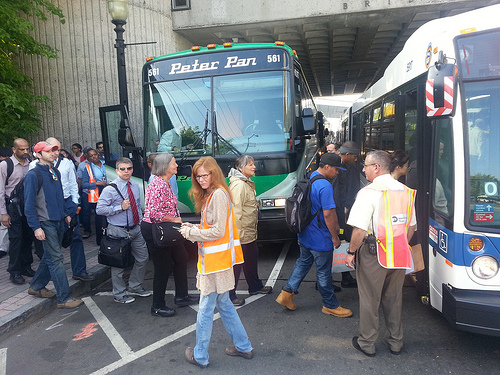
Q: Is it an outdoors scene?
A: Yes, it is outdoors.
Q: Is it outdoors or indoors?
A: It is outdoors.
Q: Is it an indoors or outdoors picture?
A: It is outdoors.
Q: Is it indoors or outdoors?
A: It is outdoors.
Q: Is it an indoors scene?
A: No, it is outdoors.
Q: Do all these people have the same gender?
A: No, they are both male and female.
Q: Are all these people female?
A: No, they are both male and female.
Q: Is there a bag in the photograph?
A: Yes, there is a bag.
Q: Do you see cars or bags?
A: Yes, there is a bag.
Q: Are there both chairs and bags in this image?
A: No, there is a bag but no chairs.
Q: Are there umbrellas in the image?
A: No, there are no umbrellas.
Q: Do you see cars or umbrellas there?
A: No, there are no umbrellas or cars.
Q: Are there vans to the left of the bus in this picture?
A: No, there is a bag to the left of the bus.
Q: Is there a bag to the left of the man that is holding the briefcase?
A: Yes, there is a bag to the left of the man.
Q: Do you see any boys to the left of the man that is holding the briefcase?
A: No, there is a bag to the left of the man.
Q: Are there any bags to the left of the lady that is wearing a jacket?
A: Yes, there is a bag to the left of the lady.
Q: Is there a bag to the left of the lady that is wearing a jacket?
A: Yes, there is a bag to the left of the lady.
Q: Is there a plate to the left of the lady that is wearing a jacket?
A: No, there is a bag to the left of the lady.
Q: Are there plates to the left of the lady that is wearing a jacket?
A: No, there is a bag to the left of the lady.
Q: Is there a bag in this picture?
A: Yes, there is a bag.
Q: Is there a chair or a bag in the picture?
A: Yes, there is a bag.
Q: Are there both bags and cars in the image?
A: No, there is a bag but no cars.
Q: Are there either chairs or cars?
A: No, there are no cars or chairs.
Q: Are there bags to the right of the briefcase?
A: Yes, there is a bag to the right of the briefcase.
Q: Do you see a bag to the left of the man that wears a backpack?
A: Yes, there is a bag to the left of the man.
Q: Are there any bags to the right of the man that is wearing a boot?
A: No, the bag is to the left of the man.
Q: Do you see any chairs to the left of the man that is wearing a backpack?
A: No, there is a bag to the left of the man.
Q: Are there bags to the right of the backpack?
A: No, the bag is to the left of the backpack.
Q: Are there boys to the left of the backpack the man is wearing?
A: No, there is a bag to the left of the backpack.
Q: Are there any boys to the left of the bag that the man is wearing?
A: No, there is a bag to the left of the backpack.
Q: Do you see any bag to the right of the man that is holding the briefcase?
A: Yes, there is a bag to the right of the man.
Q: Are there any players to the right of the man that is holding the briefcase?
A: No, there is a bag to the right of the man.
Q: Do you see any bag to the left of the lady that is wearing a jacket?
A: Yes, there is a bag to the left of the lady.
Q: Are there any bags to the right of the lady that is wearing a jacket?
A: No, the bag is to the left of the lady.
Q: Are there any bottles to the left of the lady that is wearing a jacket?
A: No, there is a bag to the left of the lady.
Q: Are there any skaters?
A: No, there are no skaters.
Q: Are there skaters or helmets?
A: No, there are no skaters or helmets.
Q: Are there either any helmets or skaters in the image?
A: No, there are no skaters or helmets.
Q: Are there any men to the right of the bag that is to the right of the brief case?
A: Yes, there is a man to the right of the bag.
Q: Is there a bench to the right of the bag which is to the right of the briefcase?
A: No, there is a man to the right of the bag.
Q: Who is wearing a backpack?
A: The man is wearing a backpack.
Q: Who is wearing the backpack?
A: The man is wearing a backpack.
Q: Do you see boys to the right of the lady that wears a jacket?
A: No, there is a man to the right of the lady.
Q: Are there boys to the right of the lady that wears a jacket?
A: No, there is a man to the right of the lady.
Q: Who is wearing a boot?
A: The man is wearing a boot.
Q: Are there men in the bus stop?
A: Yes, there is a man in the bus stop.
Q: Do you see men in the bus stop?
A: Yes, there is a man in the bus stop.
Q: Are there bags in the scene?
A: Yes, there is a bag.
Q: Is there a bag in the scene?
A: Yes, there is a bag.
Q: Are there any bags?
A: Yes, there is a bag.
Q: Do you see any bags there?
A: Yes, there is a bag.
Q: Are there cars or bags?
A: Yes, there is a bag.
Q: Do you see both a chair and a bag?
A: No, there is a bag but no chairs.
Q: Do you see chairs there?
A: No, there are no chairs.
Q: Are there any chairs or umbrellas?
A: No, there are no chairs or umbrellas.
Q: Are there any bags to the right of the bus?
A: No, the bag is to the left of the bus.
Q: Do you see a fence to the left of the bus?
A: No, there is a bag to the left of the bus.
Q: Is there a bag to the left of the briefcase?
A: Yes, there is a bag to the left of the briefcase.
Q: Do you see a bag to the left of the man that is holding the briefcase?
A: Yes, there is a bag to the left of the man.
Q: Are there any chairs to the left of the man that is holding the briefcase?
A: No, there is a bag to the left of the man.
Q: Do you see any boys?
A: No, there are no boys.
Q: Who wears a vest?
A: The man wears a vest.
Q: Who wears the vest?
A: The man wears a vest.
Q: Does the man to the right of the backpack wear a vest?
A: Yes, the man wears a vest.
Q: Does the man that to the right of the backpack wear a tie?
A: No, the man wears a vest.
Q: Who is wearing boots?
A: The man is wearing boots.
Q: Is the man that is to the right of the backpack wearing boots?
A: Yes, the man is wearing boots.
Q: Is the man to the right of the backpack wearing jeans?
A: No, the man is wearing boots.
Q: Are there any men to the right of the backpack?
A: Yes, there is a man to the right of the backpack.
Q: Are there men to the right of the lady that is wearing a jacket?
A: Yes, there is a man to the right of the lady.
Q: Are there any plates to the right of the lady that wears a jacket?
A: No, there is a man to the right of the lady.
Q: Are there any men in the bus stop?
A: Yes, there is a man in the bus stop.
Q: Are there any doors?
A: Yes, there is a door.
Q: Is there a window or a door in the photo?
A: Yes, there is a door.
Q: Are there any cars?
A: No, there are no cars.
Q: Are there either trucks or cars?
A: No, there are no cars or trucks.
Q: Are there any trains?
A: No, there are no trains.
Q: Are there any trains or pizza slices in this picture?
A: No, there are no trains or pizza slices.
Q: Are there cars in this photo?
A: No, there are no cars.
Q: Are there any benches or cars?
A: No, there are no cars or benches.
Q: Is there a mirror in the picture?
A: Yes, there is a mirror.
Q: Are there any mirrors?
A: Yes, there is a mirror.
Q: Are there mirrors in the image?
A: Yes, there is a mirror.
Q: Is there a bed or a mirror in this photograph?
A: Yes, there is a mirror.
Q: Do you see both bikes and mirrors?
A: No, there is a mirror but no bikes.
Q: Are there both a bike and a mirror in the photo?
A: No, there is a mirror but no bikes.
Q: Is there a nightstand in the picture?
A: No, there are no nightstands.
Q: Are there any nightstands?
A: No, there are no nightstands.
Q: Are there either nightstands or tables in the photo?
A: No, there are no nightstands or tables.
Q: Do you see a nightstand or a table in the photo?
A: No, there are no nightstands or tables.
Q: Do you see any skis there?
A: No, there are no skis.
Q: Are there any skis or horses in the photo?
A: No, there are no skis or horses.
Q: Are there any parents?
A: No, there are no parents.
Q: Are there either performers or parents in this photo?
A: No, there are no parents or performers.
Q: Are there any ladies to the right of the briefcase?
A: Yes, there is a lady to the right of the briefcase.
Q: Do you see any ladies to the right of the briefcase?
A: Yes, there is a lady to the right of the briefcase.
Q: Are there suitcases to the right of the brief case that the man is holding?
A: No, there is a lady to the right of the briefcase.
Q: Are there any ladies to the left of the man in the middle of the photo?
A: Yes, there is a lady to the left of the man.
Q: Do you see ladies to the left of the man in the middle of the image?
A: Yes, there is a lady to the left of the man.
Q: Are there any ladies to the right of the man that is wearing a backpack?
A: No, the lady is to the left of the man.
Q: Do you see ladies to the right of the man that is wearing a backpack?
A: No, the lady is to the left of the man.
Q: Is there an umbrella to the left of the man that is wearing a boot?
A: No, there is a lady to the left of the man.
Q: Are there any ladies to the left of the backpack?
A: Yes, there is a lady to the left of the backpack.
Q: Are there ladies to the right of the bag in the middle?
A: No, the lady is to the left of the backpack.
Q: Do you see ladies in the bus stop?
A: Yes, there is a lady in the bus stop.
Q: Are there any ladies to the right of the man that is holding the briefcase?
A: Yes, there is a lady to the right of the man.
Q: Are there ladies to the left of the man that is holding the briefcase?
A: No, the lady is to the right of the man.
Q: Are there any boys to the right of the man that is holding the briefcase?
A: No, there is a lady to the right of the man.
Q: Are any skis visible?
A: No, there are no skis.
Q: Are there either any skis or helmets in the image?
A: No, there are no skis or helmets.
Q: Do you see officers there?
A: No, there are no officers.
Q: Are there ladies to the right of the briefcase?
A: Yes, there is a lady to the right of the briefcase.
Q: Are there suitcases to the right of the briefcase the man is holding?
A: No, there is a lady to the right of the briefcase.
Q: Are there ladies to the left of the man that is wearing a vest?
A: Yes, there is a lady to the left of the man.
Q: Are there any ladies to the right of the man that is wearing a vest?
A: No, the lady is to the left of the man.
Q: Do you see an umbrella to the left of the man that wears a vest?
A: No, there is a lady to the left of the man.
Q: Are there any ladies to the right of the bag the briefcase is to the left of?
A: Yes, there is a lady to the right of the bag.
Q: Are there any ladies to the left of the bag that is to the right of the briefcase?
A: No, the lady is to the right of the bag.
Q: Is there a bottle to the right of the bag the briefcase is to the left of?
A: No, there is a lady to the right of the bag.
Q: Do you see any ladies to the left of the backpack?
A: Yes, there is a lady to the left of the backpack.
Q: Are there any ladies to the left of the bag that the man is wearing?
A: Yes, there is a lady to the left of the backpack.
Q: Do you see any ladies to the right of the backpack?
A: No, the lady is to the left of the backpack.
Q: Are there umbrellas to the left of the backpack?
A: No, there is a lady to the left of the backpack.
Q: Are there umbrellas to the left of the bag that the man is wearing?
A: No, there is a lady to the left of the backpack.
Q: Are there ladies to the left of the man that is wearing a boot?
A: Yes, there is a lady to the left of the man.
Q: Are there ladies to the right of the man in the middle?
A: No, the lady is to the left of the man.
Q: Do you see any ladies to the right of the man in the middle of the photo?
A: No, the lady is to the left of the man.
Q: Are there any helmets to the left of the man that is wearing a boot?
A: No, there is a lady to the left of the man.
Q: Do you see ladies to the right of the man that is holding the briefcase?
A: Yes, there is a lady to the right of the man.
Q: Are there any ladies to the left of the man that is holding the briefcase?
A: No, the lady is to the right of the man.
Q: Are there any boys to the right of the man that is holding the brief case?
A: No, there is a lady to the right of the man.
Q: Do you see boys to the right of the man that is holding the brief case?
A: No, there is a lady to the right of the man.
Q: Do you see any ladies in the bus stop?
A: Yes, there is a lady in the bus stop.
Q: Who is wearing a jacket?
A: The lady is wearing a jacket.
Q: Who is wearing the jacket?
A: The lady is wearing a jacket.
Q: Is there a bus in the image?
A: Yes, there is a bus.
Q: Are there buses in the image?
A: Yes, there is a bus.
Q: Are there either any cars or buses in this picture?
A: Yes, there is a bus.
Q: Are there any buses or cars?
A: Yes, there is a bus.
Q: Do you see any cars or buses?
A: Yes, there is a bus.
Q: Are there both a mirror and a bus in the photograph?
A: Yes, there are both a bus and a mirror.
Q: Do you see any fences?
A: No, there are no fences.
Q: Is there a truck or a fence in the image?
A: No, there are no fences or trucks.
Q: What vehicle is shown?
A: The vehicle is a bus.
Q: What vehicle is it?
A: The vehicle is a bus.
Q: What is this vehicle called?
A: This is a bus.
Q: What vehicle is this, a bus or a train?
A: This is a bus.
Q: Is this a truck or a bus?
A: This is a bus.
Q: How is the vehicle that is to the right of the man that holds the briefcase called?
A: The vehicle is a bus.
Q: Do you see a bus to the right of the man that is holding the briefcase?
A: Yes, there is a bus to the right of the man.